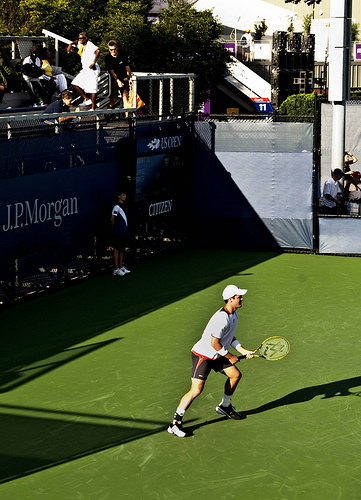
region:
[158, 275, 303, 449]
This is a person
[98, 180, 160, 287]
This is a person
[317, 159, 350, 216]
This is a person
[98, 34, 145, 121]
This is a person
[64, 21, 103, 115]
This is a person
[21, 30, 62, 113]
This is a person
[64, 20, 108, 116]
This is a person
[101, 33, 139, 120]
This is a person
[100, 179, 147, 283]
This is a person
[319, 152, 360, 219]
This is a person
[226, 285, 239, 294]
WHITE CAP ON MAN HEAD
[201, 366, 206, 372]
MAN HAS ON BLACK SHORTS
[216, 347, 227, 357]
MAN HAS ON A WHITE WRIST BAND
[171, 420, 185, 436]
MAN HAS ON TENNIS SHOES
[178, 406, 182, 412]
MAN SOCKS ARE WHITE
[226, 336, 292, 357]
MAN HOLDING A TENNIS RACKET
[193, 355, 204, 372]
MAN HAS A RED AND WHITE STRIPE ON SIDE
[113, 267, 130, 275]
MAN HAS ON WHITE TENNIS SHOES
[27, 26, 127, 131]
PEOPLE IN THE STAND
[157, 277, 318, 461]
person on the tennis court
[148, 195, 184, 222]
logo on the banner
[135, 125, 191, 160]
logo on the banner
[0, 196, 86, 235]
logo on the banner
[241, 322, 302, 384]
tennis racquet in the hand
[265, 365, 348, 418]
shadow on the court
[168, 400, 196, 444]
leg of the man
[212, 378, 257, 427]
leg of the man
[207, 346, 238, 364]
arm of the man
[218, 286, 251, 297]
hat of the man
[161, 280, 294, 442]
A man is playing tennis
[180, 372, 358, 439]
A man's shadow on the court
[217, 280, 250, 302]
A hat is white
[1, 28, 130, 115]
Spectators are watching the tennis game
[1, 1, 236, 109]
Green leaves on trees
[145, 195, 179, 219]
The word CITIZEN on a wall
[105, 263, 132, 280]
A pair of white sneakers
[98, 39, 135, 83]
Person wearing a black shirt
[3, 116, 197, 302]
A blue wall behind a person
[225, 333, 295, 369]
Tennis racket in two hands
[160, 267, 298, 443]
tennis player holding a racket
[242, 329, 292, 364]
the racket is green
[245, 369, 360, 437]
a shadow cast on the grass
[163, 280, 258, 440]
tennis player wears a white top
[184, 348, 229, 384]
short with red stripes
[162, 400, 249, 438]
a pair of blue shoes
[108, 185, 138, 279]
boy stands on side a tennis court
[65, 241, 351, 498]
floor of tennis court is green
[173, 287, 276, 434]
the man is playing tennis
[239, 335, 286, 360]
the racket is being held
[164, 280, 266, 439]
man playing tennis match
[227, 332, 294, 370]
man holding tennis racket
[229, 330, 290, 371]
tennis racket is yellow and black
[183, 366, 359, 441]
shadow of player on ground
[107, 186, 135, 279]
lady standing by wall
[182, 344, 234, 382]
player wearing pair of shorts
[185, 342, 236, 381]
players shorts are black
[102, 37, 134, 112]
man standing behind railing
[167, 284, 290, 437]
Guy in a white shirt and a white cap playing tennis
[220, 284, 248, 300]
Solid white ball cap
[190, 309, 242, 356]
White shirt with red trim